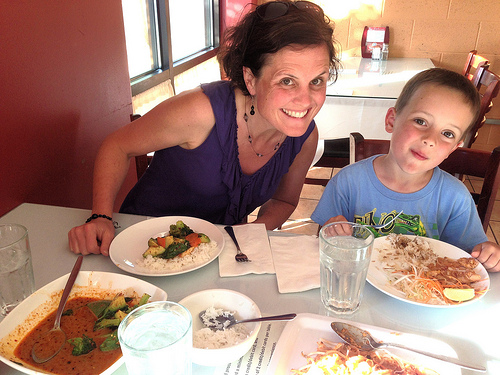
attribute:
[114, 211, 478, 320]
plate — white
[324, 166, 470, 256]
tshirt — blue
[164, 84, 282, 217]
blouse — purple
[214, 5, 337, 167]
woman — smiling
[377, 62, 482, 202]
boy — eating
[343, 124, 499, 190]
chair — wooden